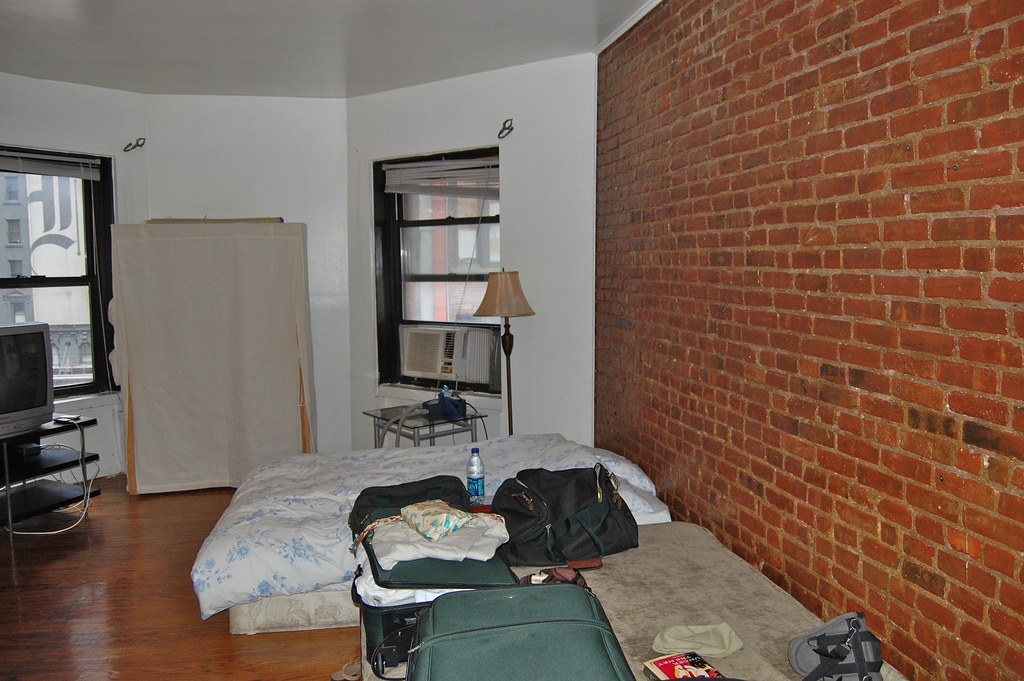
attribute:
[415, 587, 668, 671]
luggage — blue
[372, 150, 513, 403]
window — raised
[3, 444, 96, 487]
shelf — black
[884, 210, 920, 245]
brick — red, hard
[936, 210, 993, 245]
brick — red, hard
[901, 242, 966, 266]
brick — red, hard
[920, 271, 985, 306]
brick — red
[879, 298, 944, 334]
brick — red, hard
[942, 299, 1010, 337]
brick — red, hard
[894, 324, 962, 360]
brick — hard, red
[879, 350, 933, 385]
brick — red, hard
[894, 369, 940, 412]
brick — red, hard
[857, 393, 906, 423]
brick — red, hard